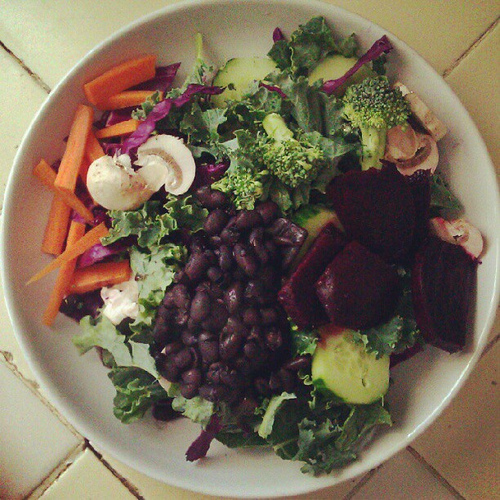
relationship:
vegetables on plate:
[88, 60, 371, 146] [210, 0, 217, 9]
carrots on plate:
[76, 49, 154, 97] [210, 0, 217, 9]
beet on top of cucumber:
[118, 94, 178, 127] [325, 363, 391, 399]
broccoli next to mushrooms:
[210, 126, 319, 168] [72, 134, 211, 199]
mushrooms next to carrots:
[72, 134, 211, 199] [76, 49, 154, 97]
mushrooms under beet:
[72, 134, 211, 199] [118, 94, 178, 127]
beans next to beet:
[193, 273, 279, 318] [118, 94, 178, 127]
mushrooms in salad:
[72, 134, 211, 199] [64, 110, 365, 267]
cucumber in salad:
[325, 363, 391, 399] [64, 110, 365, 267]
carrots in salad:
[76, 49, 154, 97] [64, 110, 365, 267]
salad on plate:
[64, 110, 365, 267] [210, 0, 217, 9]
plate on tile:
[210, 0, 217, 9] [0, 34, 42, 83]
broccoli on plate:
[210, 126, 319, 168] [210, 0, 217, 9]